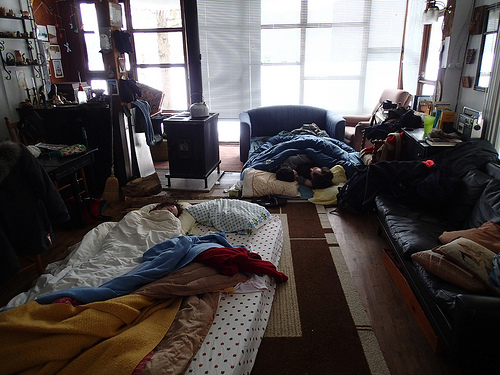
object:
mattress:
[0, 200, 285, 374]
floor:
[380, 274, 424, 353]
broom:
[100, 84, 122, 203]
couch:
[375, 172, 499, 360]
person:
[273, 163, 302, 184]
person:
[305, 163, 336, 187]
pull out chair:
[241, 104, 347, 204]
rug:
[282, 202, 386, 374]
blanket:
[195, 248, 289, 285]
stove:
[162, 111, 222, 191]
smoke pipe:
[179, 1, 205, 105]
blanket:
[0, 293, 182, 374]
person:
[149, 201, 183, 219]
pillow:
[186, 198, 273, 233]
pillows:
[432, 235, 497, 289]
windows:
[301, 0, 369, 25]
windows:
[299, 24, 366, 80]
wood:
[145, 181, 157, 190]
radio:
[455, 106, 484, 140]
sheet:
[186, 215, 284, 375]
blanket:
[34, 233, 247, 306]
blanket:
[236, 129, 364, 169]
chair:
[343, 89, 411, 146]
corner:
[408, 4, 498, 97]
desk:
[400, 127, 463, 149]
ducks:
[454, 242, 487, 259]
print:
[223, 309, 228, 313]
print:
[235, 317, 238, 322]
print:
[205, 357, 212, 361]